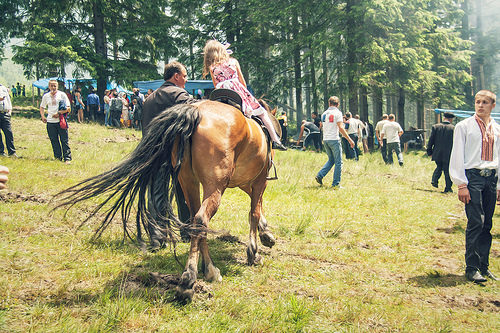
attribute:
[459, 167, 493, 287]
pants — black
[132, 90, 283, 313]
horse — brown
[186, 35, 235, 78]
lady — young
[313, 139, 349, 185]
pants — faded, blue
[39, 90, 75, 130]
ankara shirt — white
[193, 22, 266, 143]
girl — little, blonde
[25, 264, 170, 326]
field — grassy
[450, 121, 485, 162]
shirt — long sleeved, white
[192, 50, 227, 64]
hair — blond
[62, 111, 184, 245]
tail — full,  flowing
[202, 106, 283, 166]
coat — shiney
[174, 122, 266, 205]
horse — big, brown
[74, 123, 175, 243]
tail — large, dark, hairy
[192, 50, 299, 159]
girl — blonde, little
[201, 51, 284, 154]
girl — blonde, little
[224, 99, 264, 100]
dress — pink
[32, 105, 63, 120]
t-shirt — white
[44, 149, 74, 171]
pants — black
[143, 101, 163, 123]
t-shirt — gray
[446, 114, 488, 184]
shirt — man's,  white and pink,  tee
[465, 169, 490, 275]
jeans —   blue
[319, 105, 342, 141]
shirt — tee,  man's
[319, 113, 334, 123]
flag —  blue, white and red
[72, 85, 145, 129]
people —  a bunch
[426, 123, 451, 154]
jacket —  black,  man's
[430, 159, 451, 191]
pants —  black,  man's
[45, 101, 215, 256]
tail —  one,  dark,  fanned out,  horse's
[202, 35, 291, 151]
girl —  blonde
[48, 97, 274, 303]
horse — brown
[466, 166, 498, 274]
pants —  dark,  man's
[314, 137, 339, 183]
jeans —  man's,  blue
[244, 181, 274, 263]
legs —  two, the front,  sunlit,  horse's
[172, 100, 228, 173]
behind —  horse's,  one,  light brown,  sunlit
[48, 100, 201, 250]
tail —  black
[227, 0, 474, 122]
trees —  green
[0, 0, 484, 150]
trees — tall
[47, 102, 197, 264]
tail — black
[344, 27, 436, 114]
pine trees — green, tall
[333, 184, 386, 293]
field — grassy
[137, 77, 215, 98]
truck — blue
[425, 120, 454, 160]
jacket — black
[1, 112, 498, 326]
floor — green, yellow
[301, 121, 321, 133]
shirt — black